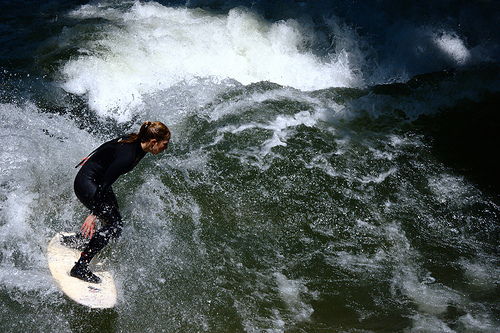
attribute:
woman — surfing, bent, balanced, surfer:
[64, 120, 171, 283]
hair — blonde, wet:
[123, 121, 173, 143]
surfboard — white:
[46, 231, 117, 310]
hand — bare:
[80, 214, 97, 240]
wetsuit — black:
[72, 136, 149, 284]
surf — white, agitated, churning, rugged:
[60, 3, 356, 122]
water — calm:
[319, 296, 405, 328]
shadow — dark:
[421, 98, 500, 201]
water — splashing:
[2, 99, 48, 311]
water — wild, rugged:
[3, 4, 497, 332]